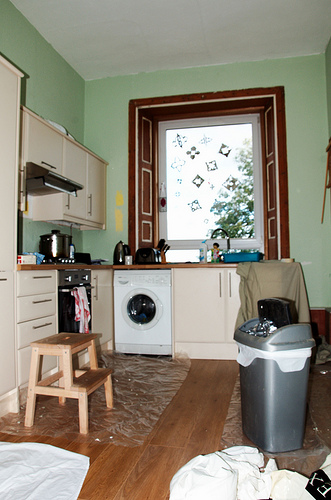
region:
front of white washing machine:
[107, 267, 176, 360]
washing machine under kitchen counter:
[107, 260, 176, 361]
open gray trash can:
[229, 293, 319, 459]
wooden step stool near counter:
[17, 326, 121, 432]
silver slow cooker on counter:
[35, 225, 77, 263]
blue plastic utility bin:
[219, 248, 262, 265]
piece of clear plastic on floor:
[2, 329, 193, 447]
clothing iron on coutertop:
[111, 239, 131, 268]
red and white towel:
[69, 286, 95, 334]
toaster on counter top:
[130, 244, 164, 263]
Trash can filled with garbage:
[233, 320, 311, 454]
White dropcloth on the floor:
[0, 441, 91, 498]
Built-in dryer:
[112, 268, 170, 355]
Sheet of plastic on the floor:
[0, 349, 192, 443]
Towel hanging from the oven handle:
[71, 285, 93, 331]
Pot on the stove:
[35, 227, 71, 261]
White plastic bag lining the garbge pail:
[236, 341, 312, 371]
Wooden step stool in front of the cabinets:
[25, 331, 114, 432]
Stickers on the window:
[166, 138, 234, 223]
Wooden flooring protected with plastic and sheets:
[1, 315, 330, 497]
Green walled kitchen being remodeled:
[0, 0, 330, 499]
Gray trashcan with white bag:
[231, 291, 314, 453]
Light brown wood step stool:
[22, 329, 115, 434]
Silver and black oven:
[55, 267, 92, 334]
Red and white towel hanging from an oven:
[70, 284, 92, 333]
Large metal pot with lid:
[37, 227, 72, 258]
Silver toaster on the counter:
[132, 244, 163, 263]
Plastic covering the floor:
[6, 348, 192, 447]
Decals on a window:
[168, 132, 240, 214]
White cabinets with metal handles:
[20, 106, 108, 233]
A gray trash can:
[230, 290, 317, 459]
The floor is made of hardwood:
[0, 343, 329, 499]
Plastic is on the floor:
[0, 342, 197, 455]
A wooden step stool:
[19, 325, 128, 443]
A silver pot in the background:
[34, 225, 76, 266]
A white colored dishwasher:
[107, 264, 179, 359]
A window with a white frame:
[152, 109, 268, 264]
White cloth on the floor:
[0, 435, 101, 498]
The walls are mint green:
[1, 2, 330, 308]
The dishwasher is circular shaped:
[118, 287, 162, 330]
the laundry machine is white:
[113, 270, 170, 349]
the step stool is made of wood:
[30, 336, 115, 435]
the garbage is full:
[236, 297, 310, 448]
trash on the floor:
[169, 443, 330, 498]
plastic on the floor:
[0, 350, 191, 442]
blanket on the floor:
[0, 438, 91, 498]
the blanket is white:
[0, 442, 91, 497]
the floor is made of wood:
[2, 359, 240, 498]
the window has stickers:
[168, 133, 240, 228]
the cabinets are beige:
[21, 108, 107, 231]